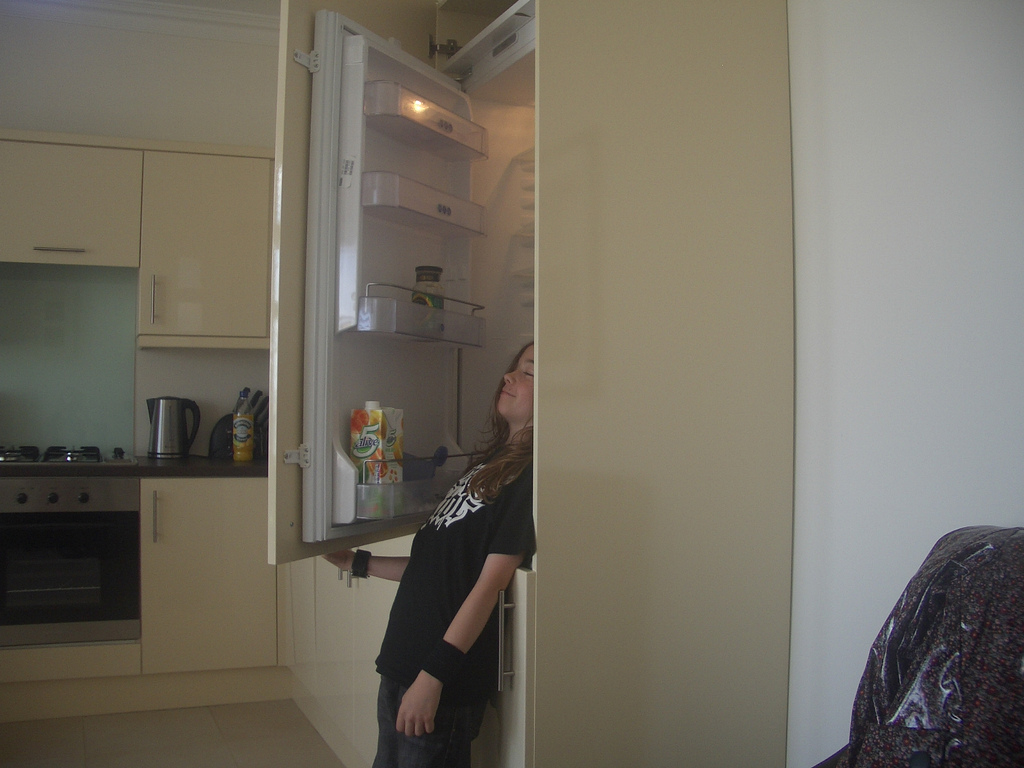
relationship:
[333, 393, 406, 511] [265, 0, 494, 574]
juice container on fridge door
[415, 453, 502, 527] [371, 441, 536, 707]
logo on shirt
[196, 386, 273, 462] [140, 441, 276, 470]
knife block on countertop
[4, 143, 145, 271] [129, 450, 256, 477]
cabinet over countertop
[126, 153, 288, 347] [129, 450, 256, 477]
cabinet over countertop